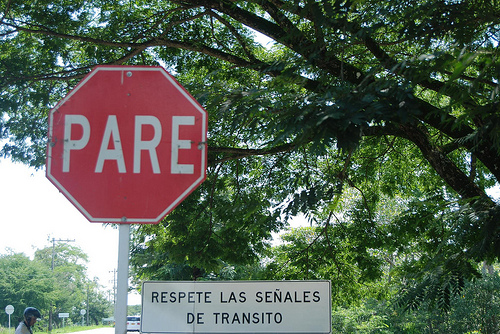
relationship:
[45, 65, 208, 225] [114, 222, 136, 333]
sign on pole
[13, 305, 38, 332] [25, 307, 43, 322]
man has helmet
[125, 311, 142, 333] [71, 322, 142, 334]
car on road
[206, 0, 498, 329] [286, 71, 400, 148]
tree has leaves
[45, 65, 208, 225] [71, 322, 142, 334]
sign on road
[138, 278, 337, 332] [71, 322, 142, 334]
sign on road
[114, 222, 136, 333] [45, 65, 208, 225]
pole holds sign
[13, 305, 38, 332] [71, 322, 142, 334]
man on road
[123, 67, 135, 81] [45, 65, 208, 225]
bolt secures sign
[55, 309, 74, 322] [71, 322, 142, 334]
sign by road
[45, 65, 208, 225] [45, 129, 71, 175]
sign has dirt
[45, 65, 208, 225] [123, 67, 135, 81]
sign has bolt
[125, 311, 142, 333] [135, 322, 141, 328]
car has lights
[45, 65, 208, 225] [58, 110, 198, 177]
sign says pare